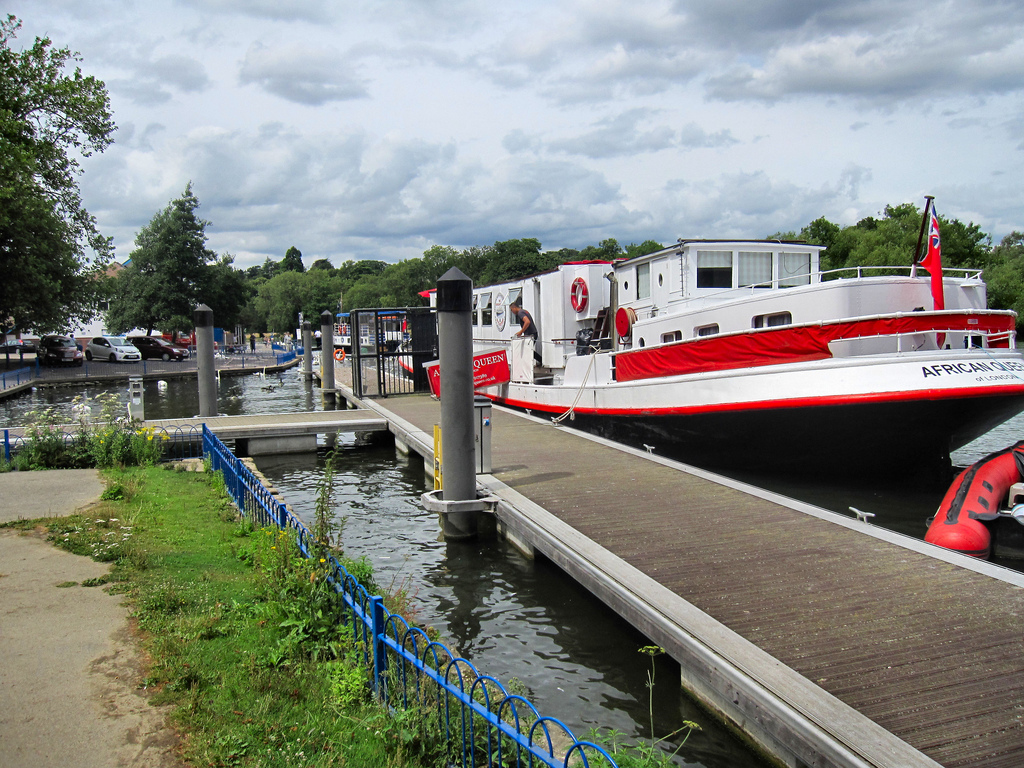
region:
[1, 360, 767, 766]
a small body of water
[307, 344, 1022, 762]
a wooden boardwalk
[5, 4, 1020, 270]
grey clouds in the sky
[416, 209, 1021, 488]
a red and white boat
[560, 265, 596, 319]
a red life preserver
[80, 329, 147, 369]
a small white car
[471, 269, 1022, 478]
man standing on a boat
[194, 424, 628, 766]
a decorative blue metal fence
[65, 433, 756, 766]
patch of grass near a body of water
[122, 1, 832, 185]
the sky is overcast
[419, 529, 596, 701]
the water is calm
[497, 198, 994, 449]
the boat is parked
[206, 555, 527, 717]
the fence is blue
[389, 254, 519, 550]
a pole is in the water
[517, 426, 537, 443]
board on the dock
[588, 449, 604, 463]
board on the dock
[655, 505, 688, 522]
board on the dock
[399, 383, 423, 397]
board on the dock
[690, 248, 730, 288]
glass window on the ship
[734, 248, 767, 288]
glass window on the ship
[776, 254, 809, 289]
glass window on the ship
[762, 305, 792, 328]
glass window on the ship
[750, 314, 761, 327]
glass window on the ship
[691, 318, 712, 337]
glass window on the ship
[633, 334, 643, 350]
glass window on the ship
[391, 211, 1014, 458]
boat in the water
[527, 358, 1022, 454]
red trim on boat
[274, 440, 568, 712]
the water is green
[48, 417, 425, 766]
a patch of grass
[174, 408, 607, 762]
a small blue fence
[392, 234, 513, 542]
post on the walkway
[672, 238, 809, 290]
window on the boat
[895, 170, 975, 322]
flag on the boat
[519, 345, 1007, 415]
white trim on boat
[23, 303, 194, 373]
cars in the background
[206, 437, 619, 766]
low blue wire fence along river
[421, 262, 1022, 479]
white red and black river boat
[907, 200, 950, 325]
red flag flying on ship deck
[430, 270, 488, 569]
grey support pole for dock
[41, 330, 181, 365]
three cars parked at edge of river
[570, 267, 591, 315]
round life ring hanging on boat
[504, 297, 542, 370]
man walking down gangplank